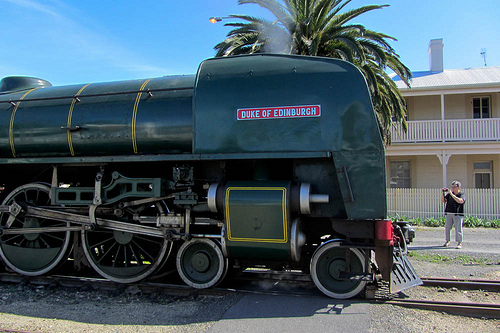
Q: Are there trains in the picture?
A: Yes, there is a train.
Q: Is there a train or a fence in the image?
A: Yes, there is a train.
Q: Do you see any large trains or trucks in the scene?
A: Yes, there is a large train.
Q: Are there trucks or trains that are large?
A: Yes, the train is large.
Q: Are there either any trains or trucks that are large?
A: Yes, the train is large.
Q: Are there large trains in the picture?
A: Yes, there is a large train.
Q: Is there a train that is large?
A: Yes, there is a train that is large.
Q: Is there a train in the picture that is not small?
A: Yes, there is a large train.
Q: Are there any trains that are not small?
A: Yes, there is a large train.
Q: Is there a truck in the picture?
A: No, there are no trucks.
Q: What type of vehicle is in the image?
A: The vehicle is a train.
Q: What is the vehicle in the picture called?
A: The vehicle is a train.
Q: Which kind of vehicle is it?
A: The vehicle is a train.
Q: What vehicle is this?
A: This is a train.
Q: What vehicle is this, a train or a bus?
A: This is a train.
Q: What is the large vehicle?
A: The vehicle is a train.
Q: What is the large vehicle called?
A: The vehicle is a train.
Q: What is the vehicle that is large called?
A: The vehicle is a train.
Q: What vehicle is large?
A: The vehicle is a train.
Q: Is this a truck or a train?
A: This is a train.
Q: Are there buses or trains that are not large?
A: No, there is a train but it is large.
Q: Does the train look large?
A: Yes, the train is large.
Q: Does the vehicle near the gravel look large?
A: Yes, the train is large.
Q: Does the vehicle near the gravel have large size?
A: Yes, the train is large.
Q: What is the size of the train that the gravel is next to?
A: The train is large.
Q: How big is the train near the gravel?
A: The train is large.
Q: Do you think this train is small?
A: No, the train is large.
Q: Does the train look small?
A: No, the train is large.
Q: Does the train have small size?
A: No, the train is large.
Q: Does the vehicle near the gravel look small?
A: No, the train is large.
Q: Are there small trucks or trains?
A: No, there is a train but it is large.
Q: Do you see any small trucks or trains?
A: No, there is a train but it is large.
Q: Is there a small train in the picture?
A: No, there is a train but it is large.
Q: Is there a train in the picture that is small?
A: No, there is a train but it is large.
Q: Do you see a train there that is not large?
A: No, there is a train but it is large.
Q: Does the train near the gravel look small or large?
A: The train is large.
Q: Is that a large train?
A: Yes, that is a large train.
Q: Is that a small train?
A: No, that is a large train.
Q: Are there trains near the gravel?
A: Yes, there is a train near the gravel.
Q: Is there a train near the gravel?
A: Yes, there is a train near the gravel.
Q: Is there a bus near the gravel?
A: No, there is a train near the gravel.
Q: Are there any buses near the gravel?
A: No, there is a train near the gravel.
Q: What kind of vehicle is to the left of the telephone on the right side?
A: The vehicle is a train.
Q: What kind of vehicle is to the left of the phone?
A: The vehicle is a train.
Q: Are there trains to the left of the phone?
A: Yes, there is a train to the left of the phone.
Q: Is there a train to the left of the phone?
A: Yes, there is a train to the left of the phone.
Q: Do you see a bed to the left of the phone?
A: No, there is a train to the left of the phone.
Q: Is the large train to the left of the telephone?
A: Yes, the train is to the left of the telephone.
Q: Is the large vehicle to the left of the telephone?
A: Yes, the train is to the left of the telephone.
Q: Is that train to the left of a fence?
A: No, the train is to the left of the telephone.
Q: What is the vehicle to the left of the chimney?
A: The vehicle is a train.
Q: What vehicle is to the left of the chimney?
A: The vehicle is a train.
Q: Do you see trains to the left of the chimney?
A: Yes, there is a train to the left of the chimney.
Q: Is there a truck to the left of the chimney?
A: No, there is a train to the left of the chimney.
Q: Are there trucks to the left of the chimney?
A: No, there is a train to the left of the chimney.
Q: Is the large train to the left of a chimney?
A: Yes, the train is to the left of a chimney.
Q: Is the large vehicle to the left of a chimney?
A: Yes, the train is to the left of a chimney.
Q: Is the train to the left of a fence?
A: No, the train is to the left of a chimney.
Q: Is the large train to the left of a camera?
A: Yes, the train is to the left of a camera.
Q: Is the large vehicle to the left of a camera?
A: Yes, the train is to the left of a camera.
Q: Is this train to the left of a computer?
A: No, the train is to the left of a camera.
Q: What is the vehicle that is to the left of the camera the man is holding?
A: The vehicle is a train.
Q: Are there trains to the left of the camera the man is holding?
A: Yes, there is a train to the left of the camera.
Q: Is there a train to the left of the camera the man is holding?
A: Yes, there is a train to the left of the camera.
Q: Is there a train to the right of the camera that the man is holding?
A: No, the train is to the left of the camera.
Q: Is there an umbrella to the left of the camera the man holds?
A: No, there is a train to the left of the camera.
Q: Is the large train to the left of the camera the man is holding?
A: Yes, the train is to the left of the camera.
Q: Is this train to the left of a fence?
A: No, the train is to the left of the camera.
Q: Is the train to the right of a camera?
A: No, the train is to the left of a camera.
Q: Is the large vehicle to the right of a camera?
A: No, the train is to the left of a camera.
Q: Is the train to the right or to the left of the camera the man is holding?
A: The train is to the left of the camera.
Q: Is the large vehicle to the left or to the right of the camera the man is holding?
A: The train is to the left of the camera.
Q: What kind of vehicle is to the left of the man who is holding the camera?
A: The vehicle is a train.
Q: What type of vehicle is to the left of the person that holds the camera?
A: The vehicle is a train.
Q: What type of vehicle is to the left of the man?
A: The vehicle is a train.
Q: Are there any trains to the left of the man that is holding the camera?
A: Yes, there is a train to the left of the man.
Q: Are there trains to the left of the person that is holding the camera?
A: Yes, there is a train to the left of the man.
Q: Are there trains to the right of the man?
A: No, the train is to the left of the man.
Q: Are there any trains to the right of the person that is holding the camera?
A: No, the train is to the left of the man.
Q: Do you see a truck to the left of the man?
A: No, there is a train to the left of the man.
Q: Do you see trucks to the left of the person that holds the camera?
A: No, there is a train to the left of the man.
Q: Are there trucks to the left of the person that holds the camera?
A: No, there is a train to the left of the man.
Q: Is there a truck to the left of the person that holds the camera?
A: No, there is a train to the left of the man.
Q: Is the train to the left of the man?
A: Yes, the train is to the left of the man.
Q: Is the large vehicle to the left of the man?
A: Yes, the train is to the left of the man.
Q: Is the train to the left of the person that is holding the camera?
A: Yes, the train is to the left of the man.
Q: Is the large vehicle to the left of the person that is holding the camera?
A: Yes, the train is to the left of the man.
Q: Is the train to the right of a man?
A: No, the train is to the left of a man.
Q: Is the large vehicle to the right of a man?
A: No, the train is to the left of a man.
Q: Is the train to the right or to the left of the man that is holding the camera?
A: The train is to the left of the man.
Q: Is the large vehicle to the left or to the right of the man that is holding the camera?
A: The train is to the left of the man.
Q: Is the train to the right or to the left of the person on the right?
A: The train is to the left of the man.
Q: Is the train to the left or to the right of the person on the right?
A: The train is to the left of the man.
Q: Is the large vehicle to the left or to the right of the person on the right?
A: The train is to the left of the man.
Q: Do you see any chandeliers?
A: No, there are no chandeliers.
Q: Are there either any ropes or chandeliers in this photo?
A: No, there are no chandeliers or ropes.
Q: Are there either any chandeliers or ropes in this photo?
A: No, there are no chandeliers or ropes.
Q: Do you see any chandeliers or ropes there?
A: No, there are no chandeliers or ropes.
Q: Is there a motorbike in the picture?
A: No, there are no motorcycles.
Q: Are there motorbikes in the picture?
A: No, there are no motorbikes.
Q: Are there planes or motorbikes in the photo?
A: No, there are no motorbikes or planes.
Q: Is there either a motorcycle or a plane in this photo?
A: No, there are no motorcycles or airplanes.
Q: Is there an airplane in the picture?
A: No, there are no airplanes.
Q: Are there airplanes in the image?
A: No, there are no airplanes.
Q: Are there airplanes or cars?
A: No, there are no airplanes or cars.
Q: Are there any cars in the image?
A: No, there are no cars.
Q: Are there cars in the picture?
A: No, there are no cars.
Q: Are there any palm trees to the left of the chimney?
A: Yes, there is a palm tree to the left of the chimney.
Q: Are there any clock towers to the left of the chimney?
A: No, there is a palm tree to the left of the chimney.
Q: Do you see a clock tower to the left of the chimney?
A: No, there is a palm tree to the left of the chimney.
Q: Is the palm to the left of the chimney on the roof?
A: Yes, the palm is to the left of the chimney.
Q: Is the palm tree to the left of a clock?
A: No, the palm tree is to the left of the chimney.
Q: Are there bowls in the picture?
A: No, there are no bowls.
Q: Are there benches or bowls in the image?
A: No, there are no bowls or benches.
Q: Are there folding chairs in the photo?
A: No, there are no folding chairs.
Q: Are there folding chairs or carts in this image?
A: No, there are no folding chairs or carts.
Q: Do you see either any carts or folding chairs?
A: No, there are no folding chairs or carts.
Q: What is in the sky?
A: The clouds are in the sky.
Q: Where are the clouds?
A: The clouds are in the sky.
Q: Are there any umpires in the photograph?
A: No, there are no umpires.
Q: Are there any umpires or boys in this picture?
A: No, there are no umpires or boys.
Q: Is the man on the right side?
A: Yes, the man is on the right of the image.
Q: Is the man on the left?
A: No, the man is on the right of the image.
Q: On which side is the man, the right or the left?
A: The man is on the right of the image.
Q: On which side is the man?
A: The man is on the right of the image.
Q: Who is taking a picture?
A: The man is taking a picture.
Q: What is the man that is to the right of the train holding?
A: The man is holding the camera.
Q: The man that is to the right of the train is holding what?
A: The man is holding the camera.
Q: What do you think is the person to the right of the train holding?
A: The man is holding the camera.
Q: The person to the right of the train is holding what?
A: The man is holding the camera.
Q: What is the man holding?
A: The man is holding the camera.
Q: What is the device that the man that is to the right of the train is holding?
A: The device is a camera.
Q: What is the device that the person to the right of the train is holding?
A: The device is a camera.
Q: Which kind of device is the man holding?
A: The man is holding the camera.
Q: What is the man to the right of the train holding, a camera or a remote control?
A: The man is holding a camera.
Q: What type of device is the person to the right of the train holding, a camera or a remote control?
A: The man is holding a camera.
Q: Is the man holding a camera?
A: Yes, the man is holding a camera.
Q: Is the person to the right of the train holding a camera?
A: Yes, the man is holding a camera.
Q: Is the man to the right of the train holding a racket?
A: No, the man is holding a camera.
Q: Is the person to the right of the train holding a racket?
A: No, the man is holding a camera.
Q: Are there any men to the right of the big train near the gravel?
A: Yes, there is a man to the right of the train.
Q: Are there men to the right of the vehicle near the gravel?
A: Yes, there is a man to the right of the train.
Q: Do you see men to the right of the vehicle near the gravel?
A: Yes, there is a man to the right of the train.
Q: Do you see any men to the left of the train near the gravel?
A: No, the man is to the right of the train.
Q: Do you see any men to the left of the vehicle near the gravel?
A: No, the man is to the right of the train.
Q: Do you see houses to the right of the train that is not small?
A: No, there is a man to the right of the train.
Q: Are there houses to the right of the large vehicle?
A: No, there is a man to the right of the train.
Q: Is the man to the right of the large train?
A: Yes, the man is to the right of the train.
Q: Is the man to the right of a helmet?
A: No, the man is to the right of the train.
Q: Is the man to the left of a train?
A: No, the man is to the right of a train.